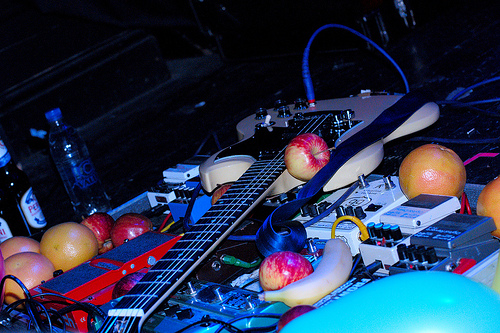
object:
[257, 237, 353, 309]
banana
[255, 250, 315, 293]
apple